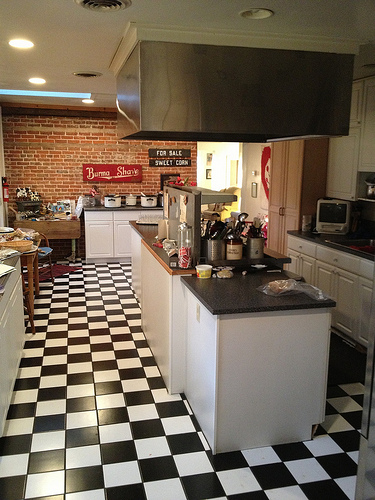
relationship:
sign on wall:
[77, 158, 143, 188] [1, 112, 199, 263]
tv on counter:
[312, 194, 352, 238] [283, 216, 373, 270]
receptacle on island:
[195, 303, 200, 324] [126, 212, 338, 452]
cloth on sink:
[350, 241, 373, 253] [324, 237, 373, 261]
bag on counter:
[259, 275, 328, 303] [179, 265, 339, 318]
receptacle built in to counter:
[194, 302, 200, 322] [179, 269, 331, 453]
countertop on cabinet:
[181, 273, 337, 315] [178, 315, 330, 455]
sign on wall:
[82, 164, 144, 185] [25, 115, 110, 191]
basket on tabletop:
[3, 238, 35, 252] [0, 227, 40, 255]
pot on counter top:
[139, 192, 157, 207] [81, 203, 164, 208]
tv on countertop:
[313, 199, 350, 237] [289, 224, 363, 251]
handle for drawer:
[330, 254, 338, 263] [310, 245, 361, 279]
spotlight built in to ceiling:
[8, 36, 35, 50] [1, 0, 99, 98]